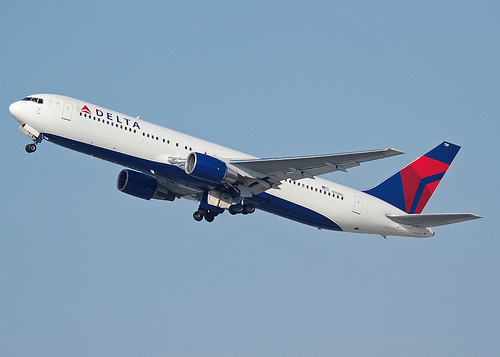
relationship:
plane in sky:
[9, 93, 482, 240] [0, 0, 499, 356]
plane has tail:
[9, 93, 482, 240] [363, 140, 481, 237]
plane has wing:
[9, 93, 482, 240] [168, 147, 406, 198]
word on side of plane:
[96, 108, 140, 128] [9, 93, 482, 240]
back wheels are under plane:
[228, 202, 256, 216] [9, 93, 482, 240]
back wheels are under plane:
[192, 206, 217, 222] [9, 93, 482, 240]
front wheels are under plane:
[25, 144, 38, 153] [9, 93, 482, 240]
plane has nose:
[9, 93, 482, 240] [8, 99, 32, 128]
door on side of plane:
[61, 101, 75, 121] [9, 93, 482, 240]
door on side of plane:
[352, 195, 365, 214] [9, 93, 482, 240]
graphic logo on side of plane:
[81, 104, 92, 116] [9, 93, 482, 240]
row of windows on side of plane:
[79, 111, 346, 201] [9, 93, 482, 240]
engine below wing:
[185, 153, 248, 186] [168, 147, 406, 198]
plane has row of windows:
[9, 93, 482, 240] [79, 111, 346, 201]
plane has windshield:
[9, 93, 482, 240] [21, 96, 45, 103]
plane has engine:
[9, 93, 482, 240] [185, 153, 248, 186]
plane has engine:
[9, 93, 482, 240] [116, 169, 175, 201]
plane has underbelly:
[9, 93, 482, 240] [41, 131, 344, 231]